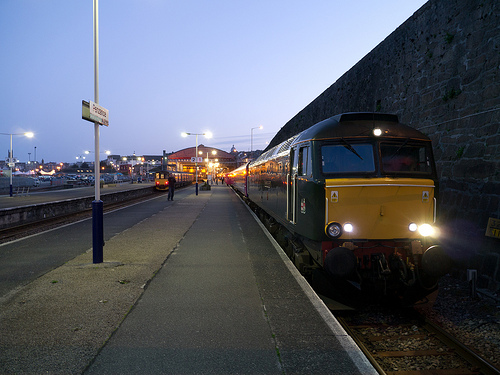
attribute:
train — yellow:
[226, 113, 438, 286]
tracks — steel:
[339, 306, 496, 373]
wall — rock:
[256, 5, 497, 287]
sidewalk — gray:
[4, 180, 347, 369]